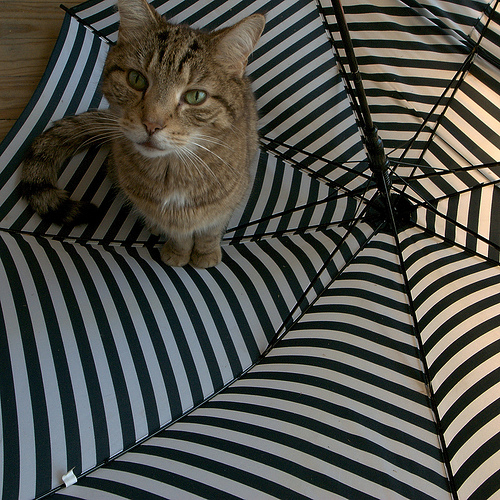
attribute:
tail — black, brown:
[24, 80, 144, 287]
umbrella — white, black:
[273, 15, 473, 308]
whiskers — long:
[172, 141, 240, 193]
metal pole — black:
[313, 5, 406, 246]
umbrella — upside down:
[26, 28, 498, 423]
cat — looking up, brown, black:
[21, 0, 265, 267]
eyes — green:
[124, 66, 209, 111]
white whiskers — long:
[51, 101, 236, 187]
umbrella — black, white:
[3, 1, 498, 498]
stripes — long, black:
[132, 158, 216, 220]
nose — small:
[137, 112, 175, 140]